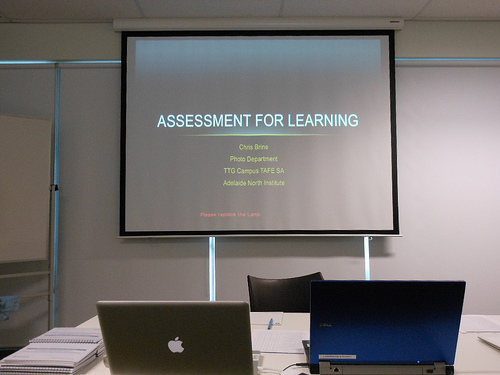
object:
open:
[299, 279, 466, 374]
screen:
[122, 23, 398, 240]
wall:
[0, 22, 499, 345]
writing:
[156, 112, 358, 129]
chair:
[245, 271, 324, 312]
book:
[0, 325, 107, 375]